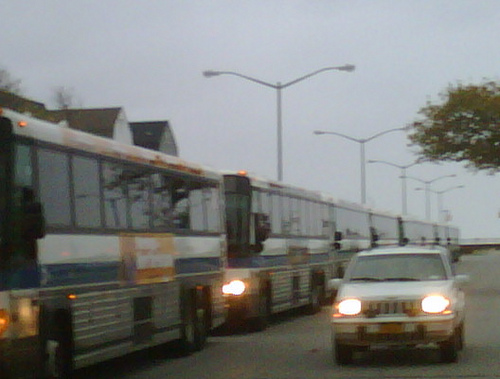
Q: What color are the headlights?
A: Yellow.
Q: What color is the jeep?
A: White.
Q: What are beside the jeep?
A: Busses.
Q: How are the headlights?
A: On.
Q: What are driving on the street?
A: Vehicles.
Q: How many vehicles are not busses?
A: One.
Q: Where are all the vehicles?
A: On the street.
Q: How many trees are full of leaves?
A: One.